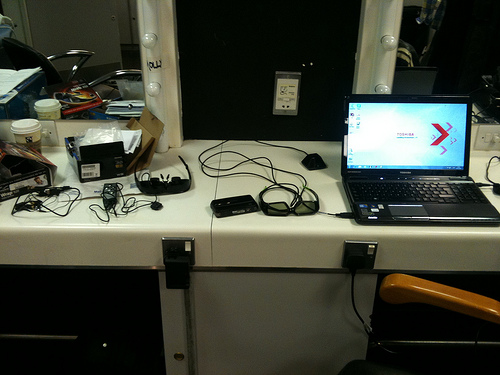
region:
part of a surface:
[221, 34, 252, 76]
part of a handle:
[398, 274, 443, 348]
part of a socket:
[339, 259, 390, 284]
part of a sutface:
[236, 314, 268, 352]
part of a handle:
[413, 277, 440, 299]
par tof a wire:
[342, 263, 401, 326]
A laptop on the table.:
[327, 102, 492, 247]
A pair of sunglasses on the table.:
[263, 177, 315, 212]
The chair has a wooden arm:
[381, 272, 493, 311]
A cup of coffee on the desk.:
[10, 107, 50, 162]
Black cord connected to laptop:
[224, 148, 354, 217]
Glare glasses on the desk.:
[130, 164, 199, 207]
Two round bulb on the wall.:
[138, 22, 160, 118]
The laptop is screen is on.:
[346, 95, 487, 223]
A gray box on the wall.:
[256, 61, 306, 117]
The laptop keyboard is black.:
[346, 86, 495, 219]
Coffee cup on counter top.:
[8, 115, 82, 170]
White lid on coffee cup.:
[4, 108, 64, 151]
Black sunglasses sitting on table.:
[127, 163, 219, 220]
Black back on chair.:
[6, 38, 73, 70]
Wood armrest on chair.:
[373, 260, 481, 352]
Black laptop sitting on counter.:
[320, 90, 480, 253]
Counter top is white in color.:
[98, 115, 439, 259]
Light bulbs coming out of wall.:
[134, 29, 169, 155]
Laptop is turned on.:
[341, 99, 486, 226]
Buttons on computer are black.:
[360, 182, 435, 202]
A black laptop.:
[341, 93, 499, 225]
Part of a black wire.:
[198, 148, 269, 179]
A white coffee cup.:
[10, 119, 43, 151]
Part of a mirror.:
[53, 33, 103, 83]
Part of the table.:
[170, 212, 195, 232]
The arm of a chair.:
[381, 273, 499, 320]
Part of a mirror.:
[433, 36, 483, 78]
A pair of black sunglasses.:
[258, 184, 321, 217]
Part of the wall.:
[216, 47, 253, 71]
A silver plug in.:
[343, 240, 377, 270]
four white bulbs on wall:
[141, 34, 406, 101]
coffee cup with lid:
[11, 117, 43, 149]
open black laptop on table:
[341, 97, 497, 228]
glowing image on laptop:
[348, 101, 468, 170]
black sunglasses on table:
[258, 182, 320, 217]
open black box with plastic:
[63, 119, 153, 181]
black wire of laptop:
[197, 139, 352, 223]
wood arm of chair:
[380, 272, 498, 325]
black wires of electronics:
[8, 179, 163, 224]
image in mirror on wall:
[3, 2, 147, 122]